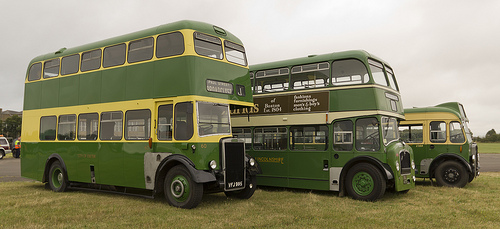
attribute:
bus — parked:
[229, 50, 416, 200]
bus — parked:
[400, 99, 482, 186]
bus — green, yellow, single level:
[400, 94, 487, 190]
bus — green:
[404, 107, 481, 184]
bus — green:
[248, 48, 419, 194]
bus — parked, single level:
[402, 100, 486, 200]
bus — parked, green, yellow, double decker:
[13, 22, 259, 217]